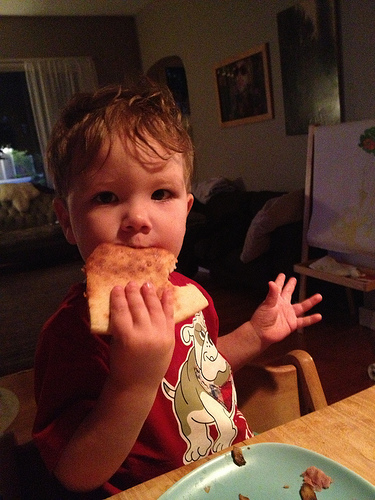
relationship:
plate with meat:
[152, 437, 373, 498] [204, 444, 333, 497]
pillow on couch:
[238, 187, 302, 269] [186, 177, 306, 313]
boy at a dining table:
[29, 80, 323, 494] [101, 379, 373, 498]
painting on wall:
[271, 3, 373, 138] [0, 0, 373, 218]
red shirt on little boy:
[20, 273, 262, 456] [31, 80, 287, 475]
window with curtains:
[1, 70, 47, 183] [21, 56, 97, 89]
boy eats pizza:
[29, 80, 323, 494] [54, 232, 230, 335]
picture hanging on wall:
[210, 42, 276, 123] [164, 14, 270, 50]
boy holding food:
[29, 80, 323, 494] [83, 245, 208, 335]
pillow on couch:
[240, 192, 301, 262] [191, 186, 304, 289]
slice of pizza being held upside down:
[105, 239, 178, 350] [90, 287, 216, 353]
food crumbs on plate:
[187, 445, 322, 500] [252, 458, 297, 484]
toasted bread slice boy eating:
[82, 242, 207, 338] [52, 86, 215, 336]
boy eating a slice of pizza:
[49, 93, 344, 448] [92, 252, 147, 351]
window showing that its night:
[1, 70, 47, 183] [18, 86, 52, 217]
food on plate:
[187, 445, 332, 497] [152, 437, 373, 498]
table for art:
[294, 243, 373, 296] [314, 129, 372, 251]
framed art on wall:
[201, 58, 268, 152] [182, 16, 257, 41]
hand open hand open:
[272, 297, 295, 312] [258, 309, 329, 385]